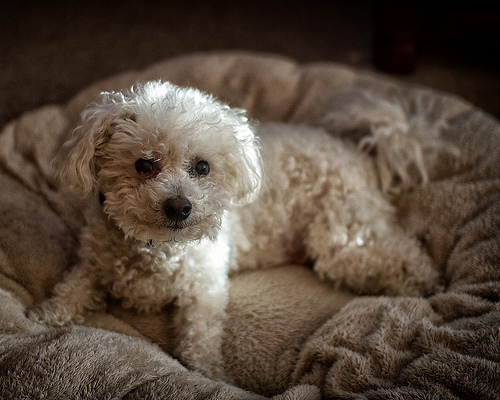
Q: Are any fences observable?
A: No, there are no fences.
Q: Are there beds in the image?
A: Yes, there is a bed.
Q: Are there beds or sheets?
A: Yes, there is a bed.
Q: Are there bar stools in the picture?
A: No, there are no bar stools.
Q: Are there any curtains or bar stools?
A: No, there are no bar stools or curtains.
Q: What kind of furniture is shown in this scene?
A: The furniture is a bed.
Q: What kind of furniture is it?
A: The piece of furniture is a bed.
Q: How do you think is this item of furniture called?
A: This is a bed.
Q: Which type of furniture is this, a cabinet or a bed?
A: This is a bed.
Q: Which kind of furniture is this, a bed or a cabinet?
A: This is a bed.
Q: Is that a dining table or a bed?
A: That is a bed.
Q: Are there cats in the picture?
A: No, there are no cats.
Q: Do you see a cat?
A: No, there are no cats.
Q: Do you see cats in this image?
A: No, there are no cats.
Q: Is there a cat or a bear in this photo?
A: No, there are no cats or bears.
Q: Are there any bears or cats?
A: No, there are no cats or bears.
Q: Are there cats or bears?
A: No, there are no cats or bears.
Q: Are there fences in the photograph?
A: No, there are no fences.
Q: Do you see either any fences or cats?
A: No, there are no fences or cats.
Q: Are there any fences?
A: No, there are no fences.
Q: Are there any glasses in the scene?
A: No, there are no glasses.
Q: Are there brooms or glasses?
A: No, there are no glasses or brooms.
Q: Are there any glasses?
A: No, there are no glasses.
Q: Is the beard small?
A: Yes, the beard is small.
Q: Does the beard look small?
A: Yes, the beard is small.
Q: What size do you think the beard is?
A: The beard is small.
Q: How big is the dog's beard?
A: The beard is small.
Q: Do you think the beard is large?
A: No, the beard is small.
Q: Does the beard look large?
A: No, the beard is small.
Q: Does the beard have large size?
A: No, the beard is small.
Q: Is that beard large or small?
A: The beard is small.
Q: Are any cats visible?
A: No, there are no cats.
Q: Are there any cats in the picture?
A: No, there are no cats.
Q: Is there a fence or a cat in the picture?
A: No, there are no cats or fences.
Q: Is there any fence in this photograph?
A: No, there are no fences.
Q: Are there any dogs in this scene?
A: Yes, there is a dog.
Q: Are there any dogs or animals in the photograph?
A: Yes, there is a dog.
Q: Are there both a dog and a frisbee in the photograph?
A: No, there is a dog but no frisbees.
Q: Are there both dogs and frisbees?
A: No, there is a dog but no frisbees.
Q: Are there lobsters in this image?
A: No, there are no lobsters.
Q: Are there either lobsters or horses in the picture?
A: No, there are no lobsters or horses.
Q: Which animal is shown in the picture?
A: The animal is a dog.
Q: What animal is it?
A: The animal is a dog.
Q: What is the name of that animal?
A: This is a dog.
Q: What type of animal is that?
A: This is a dog.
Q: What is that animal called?
A: This is a dog.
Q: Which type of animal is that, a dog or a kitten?
A: This is a dog.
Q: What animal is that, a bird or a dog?
A: That is a dog.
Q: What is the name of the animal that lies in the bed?
A: The animal is a dog.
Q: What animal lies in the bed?
A: The animal is a dog.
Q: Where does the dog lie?
A: The dog lies in the bed.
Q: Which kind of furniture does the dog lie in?
A: The dog lies in the bed.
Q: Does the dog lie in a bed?
A: Yes, the dog lies in a bed.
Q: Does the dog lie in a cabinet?
A: No, the dog lies in a bed.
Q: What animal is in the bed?
A: The dog is in the bed.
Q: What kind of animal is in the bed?
A: The animal is a dog.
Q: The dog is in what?
A: The dog is in the bed.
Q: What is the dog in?
A: The dog is in the bed.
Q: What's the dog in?
A: The dog is in the bed.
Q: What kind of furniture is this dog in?
A: The dog is in the bed.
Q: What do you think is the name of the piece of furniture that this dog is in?
A: The piece of furniture is a bed.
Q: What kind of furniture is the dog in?
A: The dog is in the bed.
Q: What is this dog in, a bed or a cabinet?
A: The dog is in a bed.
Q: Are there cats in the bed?
A: No, there is a dog in the bed.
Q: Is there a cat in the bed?
A: No, there is a dog in the bed.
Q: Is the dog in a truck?
A: No, the dog is in the bed.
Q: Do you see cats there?
A: No, there are no cats.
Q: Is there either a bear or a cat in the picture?
A: No, there are no cats or bears.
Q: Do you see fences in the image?
A: No, there are no fences.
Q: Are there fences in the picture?
A: No, there are no fences.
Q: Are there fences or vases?
A: No, there are no fences or vases.